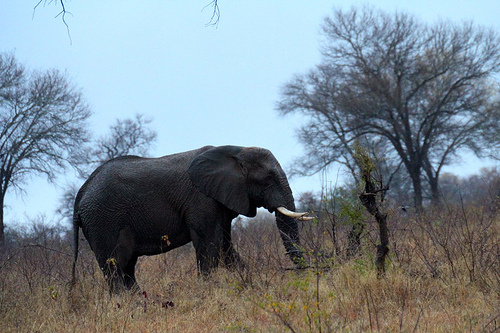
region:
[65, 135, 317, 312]
lone elephant in brush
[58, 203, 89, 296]
tail on back of elephant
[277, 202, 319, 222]
two tusks on elephant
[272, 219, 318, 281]
hanging trunk of elephant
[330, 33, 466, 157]
trees with no leaves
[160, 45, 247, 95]
pale blue daytime sky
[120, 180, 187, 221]
wrinkle skin on elephant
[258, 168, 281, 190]
eye on elephant's head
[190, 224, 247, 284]
front legs on elephant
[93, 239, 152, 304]
back legs of elephant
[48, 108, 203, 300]
Elephant in the wild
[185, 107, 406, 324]
Elephant with the tusks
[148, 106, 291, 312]
Elephants with big ears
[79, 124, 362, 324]
Large male elephant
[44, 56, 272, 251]
Trees behind the elephant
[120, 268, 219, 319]
Dry grass under the elephant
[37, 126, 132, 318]
Elephant tail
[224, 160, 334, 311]
Elephant in the wild looking for food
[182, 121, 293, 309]
Male elephant walking in the grass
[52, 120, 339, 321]
A large elephant on the planes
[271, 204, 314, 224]
pair of elephant tusks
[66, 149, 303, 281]
large grey elephant on grass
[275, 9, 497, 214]
trees bare of leaves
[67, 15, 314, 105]
clear blue cloudless sky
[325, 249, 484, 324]
dead brown grass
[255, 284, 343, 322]
small yellow flowers growing in field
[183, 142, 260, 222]
large elephant ear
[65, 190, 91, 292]
long elephant tail hanging straight down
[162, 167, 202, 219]
wrinkled grey skin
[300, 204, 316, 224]
sharp points on end of tusks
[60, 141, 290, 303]
this is an elephant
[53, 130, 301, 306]
the elephant is black in color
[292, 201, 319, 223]
the tusks are sharp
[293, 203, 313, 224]
the tusks are white in color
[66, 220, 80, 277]
the tail is long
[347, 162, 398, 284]
the branch is short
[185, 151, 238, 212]
the ear is big in size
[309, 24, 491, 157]
the tree is branchy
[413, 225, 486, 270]
the branches are brown in color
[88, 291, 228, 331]
the grass are dry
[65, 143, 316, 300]
Black elephant walking in the wild.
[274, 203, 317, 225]
Two white tusks on a black elephant.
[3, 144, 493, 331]
Elephant walking on brown grass.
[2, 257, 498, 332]
Dead grass and weeds underneath the elephant's feet.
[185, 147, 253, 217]
Black elephant's ear.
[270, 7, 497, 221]
Tree in the wild with brown leaves.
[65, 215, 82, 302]
Long black elephant's tail.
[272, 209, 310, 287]
Trunk of the elephant.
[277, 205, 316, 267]
Black trunk between the elephant's tusks.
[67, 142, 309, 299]
Black elephant in a wild park.